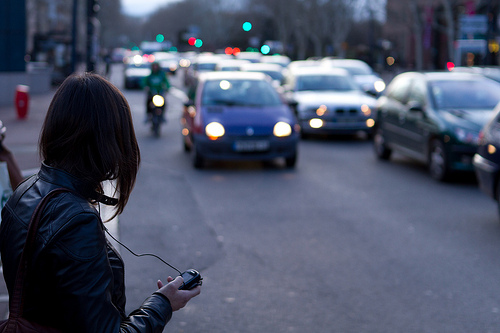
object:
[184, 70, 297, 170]
vehicle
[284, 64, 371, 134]
vehicle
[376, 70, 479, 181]
vehicle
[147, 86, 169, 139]
vehicle